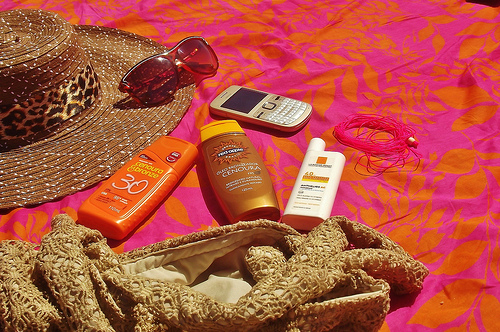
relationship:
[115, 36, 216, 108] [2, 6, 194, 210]
shades with hat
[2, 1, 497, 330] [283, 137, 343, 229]
blanket with lotion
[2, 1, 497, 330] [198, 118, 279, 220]
blanket with lotion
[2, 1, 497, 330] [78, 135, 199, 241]
blanket with bottle care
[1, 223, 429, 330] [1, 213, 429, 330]
fabric of fabric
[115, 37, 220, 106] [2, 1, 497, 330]
shades on blanket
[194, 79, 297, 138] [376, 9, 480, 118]
cell phone on blanket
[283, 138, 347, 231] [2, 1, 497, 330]
bottle care on blanket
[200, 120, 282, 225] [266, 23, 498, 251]
bottle care on blanket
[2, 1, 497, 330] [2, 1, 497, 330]
blanket on blanket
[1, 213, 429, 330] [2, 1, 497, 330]
fabric on blanket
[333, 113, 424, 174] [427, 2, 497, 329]
bracelet on blanket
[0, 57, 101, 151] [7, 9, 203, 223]
ribbon on hat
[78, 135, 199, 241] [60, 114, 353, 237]
bottle care of lotion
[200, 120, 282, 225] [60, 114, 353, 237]
bottle care of lotion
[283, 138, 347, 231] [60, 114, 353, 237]
bottle care of lotion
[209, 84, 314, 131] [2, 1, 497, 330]
cell phone on blanket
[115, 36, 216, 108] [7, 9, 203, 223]
shades on hat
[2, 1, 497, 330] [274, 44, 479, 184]
blanket on blanket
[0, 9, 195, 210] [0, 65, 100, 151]
hat with ribbon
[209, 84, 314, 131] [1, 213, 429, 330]
cell phone on fabric